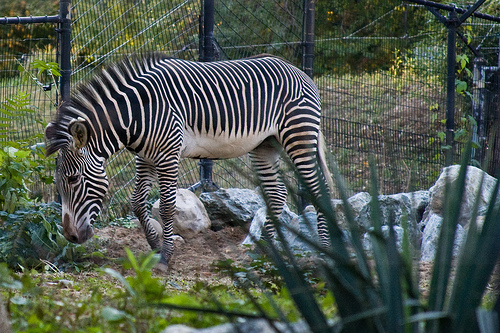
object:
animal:
[42, 53, 337, 273]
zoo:
[2, 3, 497, 332]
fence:
[0, 0, 490, 191]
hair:
[44, 50, 168, 157]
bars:
[58, 0, 77, 115]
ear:
[45, 123, 56, 139]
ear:
[67, 121, 89, 144]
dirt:
[71, 220, 280, 295]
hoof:
[147, 240, 162, 255]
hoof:
[152, 257, 173, 275]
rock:
[203, 187, 255, 227]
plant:
[8, 209, 53, 263]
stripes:
[84, 63, 156, 141]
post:
[198, 0, 219, 186]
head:
[44, 119, 117, 244]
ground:
[7, 142, 498, 332]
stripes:
[200, 63, 296, 144]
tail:
[302, 125, 336, 209]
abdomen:
[149, 115, 278, 157]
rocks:
[334, 191, 419, 231]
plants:
[111, 246, 173, 311]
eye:
[67, 175, 80, 185]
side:
[64, 140, 104, 220]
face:
[53, 123, 108, 240]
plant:
[148, 129, 495, 331]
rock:
[420, 210, 500, 263]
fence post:
[58, 3, 69, 210]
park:
[2, 1, 484, 329]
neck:
[77, 99, 136, 160]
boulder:
[150, 188, 211, 238]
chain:
[13, 55, 64, 90]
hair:
[318, 133, 336, 196]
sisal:
[456, 142, 500, 330]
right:
[353, 172, 451, 320]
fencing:
[321, 85, 441, 185]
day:
[0, 0, 499, 332]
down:
[81, 230, 116, 300]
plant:
[0, 267, 78, 329]